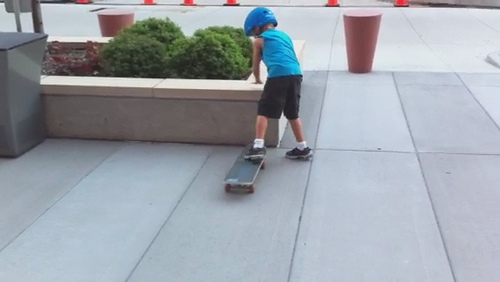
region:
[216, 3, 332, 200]
child skateboarding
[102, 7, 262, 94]
four green bushes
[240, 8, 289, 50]
child wearing a blue helmet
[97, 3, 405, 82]
two large red pots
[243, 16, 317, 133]
child wearing black shorts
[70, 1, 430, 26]
orange safety cones in the background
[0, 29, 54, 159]
grey garbage can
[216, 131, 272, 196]
black skateboard with childs foot on top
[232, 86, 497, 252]
grey sidewalk with retangular slabs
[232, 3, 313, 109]
child in blue tank top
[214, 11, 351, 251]
a young boy on a skate board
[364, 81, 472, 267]
concrete side walk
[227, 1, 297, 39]
a blue safety helmet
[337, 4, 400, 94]
a tall red pot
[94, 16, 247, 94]
four bushes ground in a raised bed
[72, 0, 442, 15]
six orange traffic cones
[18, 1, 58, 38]
small grey trunk of a tree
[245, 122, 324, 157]
white ankle socks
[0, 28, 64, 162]
a grey metal garbage can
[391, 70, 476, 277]
a shaded area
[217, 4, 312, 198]
a child on a skateboard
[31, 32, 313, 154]
an outdoor concrete planter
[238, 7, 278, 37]
a child's blue protective helmet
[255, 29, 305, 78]
a child's blue tank top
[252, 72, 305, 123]
a child's black shorts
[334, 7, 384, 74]
a red barrier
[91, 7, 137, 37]
a red barrier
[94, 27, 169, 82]
a round green bush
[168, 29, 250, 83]
a round green bush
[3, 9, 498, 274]
a grey tiled sidewalk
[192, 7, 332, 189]
a boy in blue helmet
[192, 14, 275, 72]
a boy in blue helmet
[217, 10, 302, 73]
a boy in blue helmet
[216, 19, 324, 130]
a boy in blue helmet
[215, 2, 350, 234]
a young child skateboarding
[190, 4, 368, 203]
a young boy skateboarding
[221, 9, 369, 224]
a young child with one foot on skateboard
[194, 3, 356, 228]
a young boy with one foot on skateboard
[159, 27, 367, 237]
one foot on the skateboard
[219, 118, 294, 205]
black skateboard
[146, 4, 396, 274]
a young child on a sidewalk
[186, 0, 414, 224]
a young boy on a sidewalk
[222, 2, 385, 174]
a young child with a blue helmet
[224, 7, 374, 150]
a young child with a blue shirt